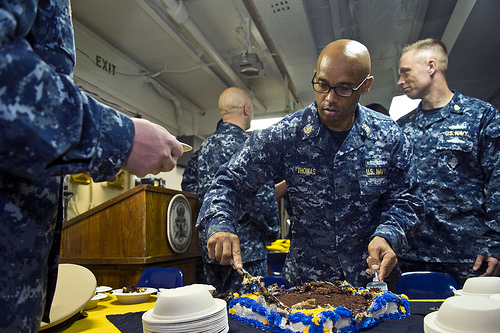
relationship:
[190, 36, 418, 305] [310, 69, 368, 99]
man wearing glasses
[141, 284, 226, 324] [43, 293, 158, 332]
bowls on table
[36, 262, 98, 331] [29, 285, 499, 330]
white plate on table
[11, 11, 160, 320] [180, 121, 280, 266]
man wearing uniform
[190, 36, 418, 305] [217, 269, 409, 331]
man cutting cake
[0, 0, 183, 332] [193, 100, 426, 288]
man in man's uniform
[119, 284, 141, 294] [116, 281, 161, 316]
cake in bowl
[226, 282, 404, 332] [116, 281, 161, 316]
cake in bowl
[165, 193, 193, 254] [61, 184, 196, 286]
emblem on podium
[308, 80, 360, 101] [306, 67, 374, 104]
frame on glasses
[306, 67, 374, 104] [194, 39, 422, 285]
glasses on man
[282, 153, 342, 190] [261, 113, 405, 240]
engraving on vest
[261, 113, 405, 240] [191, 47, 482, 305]
vest on man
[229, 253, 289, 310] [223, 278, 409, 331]
knife cutting cake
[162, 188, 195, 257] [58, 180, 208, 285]
emblem in front of podium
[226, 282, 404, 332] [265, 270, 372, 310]
cake with frosting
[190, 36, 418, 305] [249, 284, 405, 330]
man cutting cake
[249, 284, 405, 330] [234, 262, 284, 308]
cake with a knife